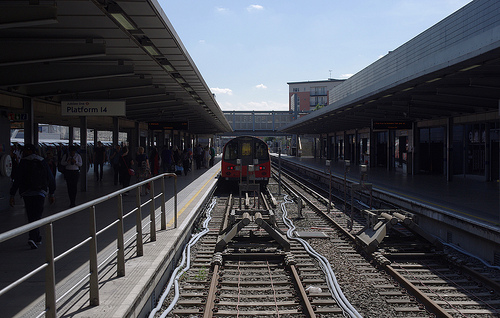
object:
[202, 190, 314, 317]
tracks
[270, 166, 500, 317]
tracks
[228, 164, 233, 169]
light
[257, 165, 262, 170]
red light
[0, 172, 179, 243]
railing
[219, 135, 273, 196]
train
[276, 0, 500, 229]
station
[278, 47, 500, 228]
walkway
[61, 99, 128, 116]
sign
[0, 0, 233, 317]
station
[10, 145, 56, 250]
people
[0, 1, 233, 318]
walkway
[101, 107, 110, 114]
number